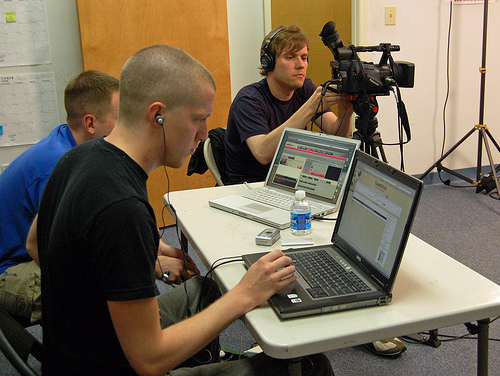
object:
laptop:
[240, 151, 423, 322]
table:
[163, 182, 499, 374]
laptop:
[209, 127, 364, 232]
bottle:
[288, 189, 313, 246]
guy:
[24, 46, 333, 375]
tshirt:
[36, 135, 161, 375]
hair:
[115, 45, 218, 132]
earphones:
[154, 110, 245, 366]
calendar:
[1, 69, 63, 151]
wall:
[2, 0, 498, 189]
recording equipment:
[310, 19, 417, 171]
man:
[2, 71, 120, 324]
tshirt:
[1, 123, 75, 275]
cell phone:
[254, 222, 282, 246]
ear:
[147, 100, 166, 130]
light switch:
[384, 4, 398, 26]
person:
[224, 21, 407, 358]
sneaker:
[360, 338, 409, 358]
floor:
[2, 175, 499, 376]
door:
[74, 0, 231, 229]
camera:
[315, 20, 417, 146]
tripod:
[346, 96, 391, 164]